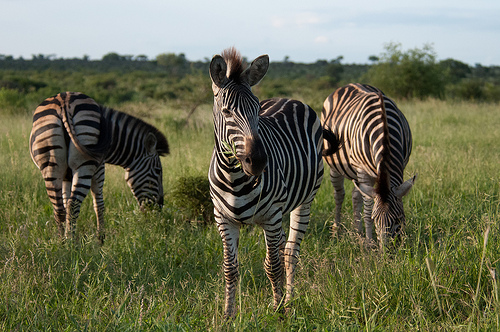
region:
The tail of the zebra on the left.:
[55, 97, 102, 165]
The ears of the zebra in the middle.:
[202, 55, 278, 87]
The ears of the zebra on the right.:
[349, 168, 417, 200]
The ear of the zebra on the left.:
[136, 132, 152, 150]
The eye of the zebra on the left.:
[136, 151, 167, 176]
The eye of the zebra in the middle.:
[214, 97, 239, 122]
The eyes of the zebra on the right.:
[365, 212, 407, 229]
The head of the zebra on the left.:
[125, 110, 167, 211]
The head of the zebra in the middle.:
[190, 52, 285, 167]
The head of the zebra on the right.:
[343, 161, 433, 256]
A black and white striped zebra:
[201, 41, 326, 310]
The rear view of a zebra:
[16, 69, 178, 266]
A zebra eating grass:
[318, 76, 435, 273]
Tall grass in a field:
[320, 262, 491, 326]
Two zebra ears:
[196, 37, 287, 120]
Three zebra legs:
[202, 217, 320, 319]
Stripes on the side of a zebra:
[268, 104, 321, 204]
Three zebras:
[18, 45, 445, 310]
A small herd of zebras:
[24, 46, 439, 307]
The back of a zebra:
[320, 77, 411, 133]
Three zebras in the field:
[47, 73, 399, 279]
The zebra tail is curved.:
[56, 101, 116, 163]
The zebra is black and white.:
[183, 74, 313, 293]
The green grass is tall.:
[52, 241, 182, 329]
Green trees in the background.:
[78, 28, 451, 85]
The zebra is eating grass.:
[341, 103, 444, 253]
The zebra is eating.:
[88, 86, 186, 240]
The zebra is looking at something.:
[158, 42, 303, 212]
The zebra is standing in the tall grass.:
[11, 77, 189, 262]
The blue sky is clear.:
[112, 11, 417, 58]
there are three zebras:
[24, 72, 416, 272]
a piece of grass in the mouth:
[201, 120, 278, 214]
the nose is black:
[222, 131, 271, 190]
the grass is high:
[225, 208, 464, 302]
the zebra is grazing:
[360, 165, 445, 255]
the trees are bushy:
[290, 45, 488, 110]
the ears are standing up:
[179, 39, 276, 94]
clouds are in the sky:
[240, 5, 460, 55]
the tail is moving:
[32, 91, 104, 171]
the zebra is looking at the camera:
[168, 40, 280, 188]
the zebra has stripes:
[29, 36, 496, 275]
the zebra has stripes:
[84, 93, 351, 329]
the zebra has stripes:
[167, 46, 377, 285]